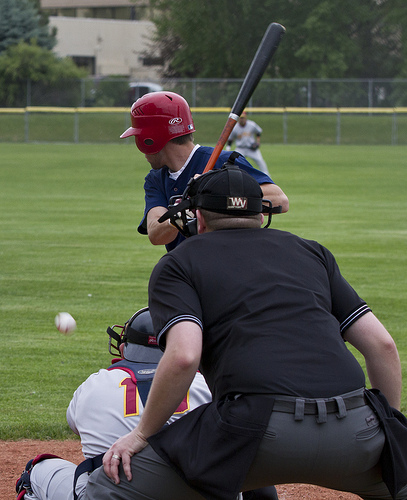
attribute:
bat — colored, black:
[202, 21, 287, 175]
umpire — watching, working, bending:
[84, 166, 405, 499]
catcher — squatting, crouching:
[16, 307, 278, 500]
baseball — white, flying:
[55, 313, 78, 336]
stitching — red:
[55, 314, 72, 333]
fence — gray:
[0, 76, 406, 147]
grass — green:
[0, 141, 406, 439]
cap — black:
[185, 166, 263, 214]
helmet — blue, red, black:
[123, 307, 164, 363]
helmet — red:
[120, 91, 196, 155]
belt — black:
[273, 394, 368, 417]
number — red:
[120, 374, 191, 417]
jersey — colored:
[66, 369, 211, 462]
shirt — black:
[148, 227, 373, 396]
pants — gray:
[82, 388, 405, 498]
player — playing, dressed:
[225, 110, 271, 177]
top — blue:
[138, 145, 275, 251]